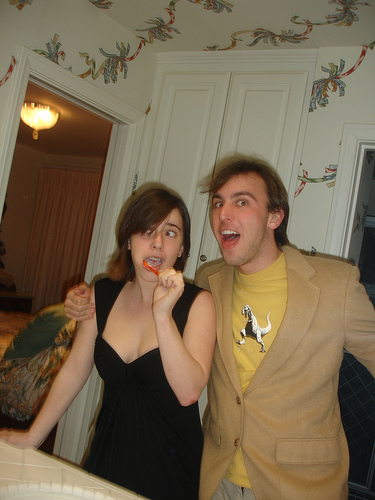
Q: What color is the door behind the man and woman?
A: White.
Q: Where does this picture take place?
A: In a bathroom.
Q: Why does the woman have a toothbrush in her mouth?
A: She is brushing her teeth.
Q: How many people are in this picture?
A: Two.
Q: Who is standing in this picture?
A: A man and woman.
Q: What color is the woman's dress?
A: Black.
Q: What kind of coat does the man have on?
A: A blazer.